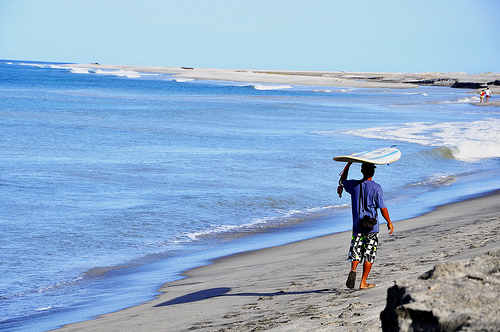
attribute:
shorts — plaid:
[347, 232, 379, 262]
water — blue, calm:
[0, 0, 500, 331]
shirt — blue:
[340, 177, 389, 235]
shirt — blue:
[338, 179, 406, 239]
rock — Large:
[378, 247, 498, 329]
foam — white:
[402, 121, 497, 159]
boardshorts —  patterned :
[346, 231, 381, 264]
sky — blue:
[0, 0, 500, 74]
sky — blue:
[4, 5, 499, 45]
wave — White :
[346, 103, 498, 170]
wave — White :
[4, 53, 448, 98]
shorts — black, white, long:
[347, 223, 377, 263]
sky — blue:
[370, 16, 427, 61]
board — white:
[330, 140, 402, 165]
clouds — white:
[258, 27, 348, 66]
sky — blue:
[19, 8, 479, 76]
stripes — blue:
[328, 131, 398, 190]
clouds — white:
[104, 63, 234, 96]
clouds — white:
[121, 50, 321, 104]